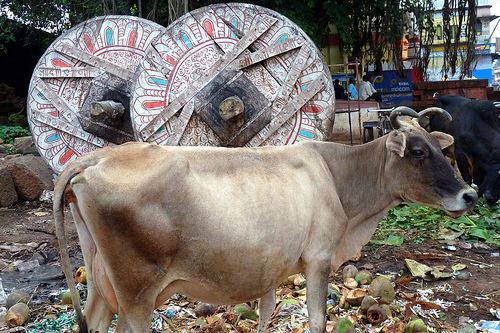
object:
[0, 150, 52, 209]
rock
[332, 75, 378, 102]
people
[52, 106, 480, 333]
cow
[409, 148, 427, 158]
eye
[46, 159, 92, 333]
tail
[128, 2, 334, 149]
colorful wheel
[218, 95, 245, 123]
axel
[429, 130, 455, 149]
ear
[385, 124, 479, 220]
cow's face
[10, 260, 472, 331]
vegetation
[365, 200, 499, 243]
vegetation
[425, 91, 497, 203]
cow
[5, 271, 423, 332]
garbage heap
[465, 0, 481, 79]
tree fronds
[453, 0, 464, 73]
tree fronds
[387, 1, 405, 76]
tree fronds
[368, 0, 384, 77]
tree fronds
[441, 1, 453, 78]
tree fronds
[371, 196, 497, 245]
pile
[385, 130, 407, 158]
ear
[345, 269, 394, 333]
fruit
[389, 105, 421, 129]
horn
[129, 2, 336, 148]
wheel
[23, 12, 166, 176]
wheel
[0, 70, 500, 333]
ground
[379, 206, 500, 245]
material